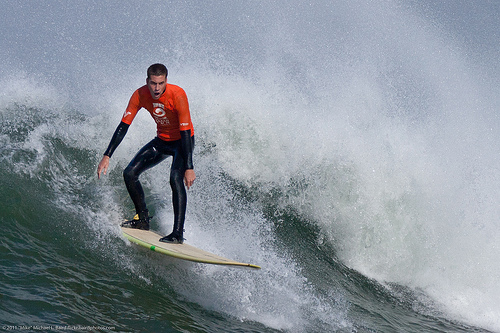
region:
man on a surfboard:
[93, 46, 268, 282]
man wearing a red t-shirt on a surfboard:
[80, 46, 242, 256]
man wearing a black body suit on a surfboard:
[86, 42, 257, 279]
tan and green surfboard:
[96, 210, 276, 285]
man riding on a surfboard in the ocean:
[92, 50, 274, 286]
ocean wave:
[242, 47, 454, 323]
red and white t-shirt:
[125, 89, 209, 154]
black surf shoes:
[114, 214, 196, 254]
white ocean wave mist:
[235, 31, 396, 252]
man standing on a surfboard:
[87, 46, 262, 288]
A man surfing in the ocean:
[100, 57, 275, 289]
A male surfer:
[95, 44, 267, 283]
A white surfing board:
[107, 196, 264, 295]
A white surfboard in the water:
[103, 204, 273, 289]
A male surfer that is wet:
[89, 58, 236, 245]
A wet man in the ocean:
[101, 59, 219, 251]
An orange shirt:
[121, 77, 204, 149]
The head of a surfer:
[140, 59, 171, 99]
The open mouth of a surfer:
[149, 88, 161, 101]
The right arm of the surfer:
[92, 89, 145, 176]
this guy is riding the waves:
[32, 29, 407, 291]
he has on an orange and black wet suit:
[99, 81, 212, 236]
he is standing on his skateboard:
[70, 38, 228, 260]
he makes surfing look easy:
[69, 57, 276, 301]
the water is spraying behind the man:
[38, 18, 270, 118]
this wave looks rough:
[244, 62, 480, 259]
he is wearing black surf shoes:
[95, 196, 285, 272]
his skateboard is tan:
[110, 219, 293, 276]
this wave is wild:
[36, 80, 378, 295]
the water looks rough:
[42, 22, 454, 282]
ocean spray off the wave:
[202, 5, 496, 230]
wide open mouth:
[152, 88, 159, 98]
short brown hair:
[147, 58, 169, 80]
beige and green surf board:
[103, 218, 255, 278]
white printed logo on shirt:
[150, 103, 170, 132]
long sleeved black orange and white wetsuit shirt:
[104, 83, 197, 171]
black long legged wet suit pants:
[123, 148, 187, 223]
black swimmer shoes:
[120, 219, 186, 243]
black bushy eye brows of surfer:
[147, 79, 169, 85]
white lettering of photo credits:
[3, 323, 115, 332]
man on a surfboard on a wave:
[74, 48, 288, 284]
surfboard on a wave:
[102, 200, 282, 285]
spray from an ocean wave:
[223, 82, 431, 282]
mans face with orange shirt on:
[91, 47, 216, 144]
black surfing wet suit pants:
[124, 131, 209, 211]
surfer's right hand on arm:
[84, 148, 112, 179]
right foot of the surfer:
[117, 205, 157, 232]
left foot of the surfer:
[163, 220, 210, 257]